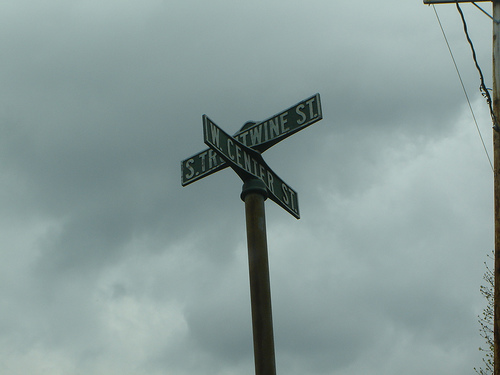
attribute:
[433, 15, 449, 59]
wire — not straight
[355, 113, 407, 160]
cloud — white, gray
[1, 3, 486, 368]
clouds — white, gray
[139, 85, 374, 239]
signs — metal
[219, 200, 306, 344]
pole — metal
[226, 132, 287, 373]
pole — metal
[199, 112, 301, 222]
street sign — green, white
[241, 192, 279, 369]
pole — metal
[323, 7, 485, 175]
cloud — dark, gray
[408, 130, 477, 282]
clouds — gray, white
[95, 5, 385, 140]
clouds — gray, white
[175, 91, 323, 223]
signs — small, green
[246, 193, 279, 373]
pole — metal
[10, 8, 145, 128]
cloud — gray, white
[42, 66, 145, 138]
cloud — gray, white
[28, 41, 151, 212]
cloud — white, gray